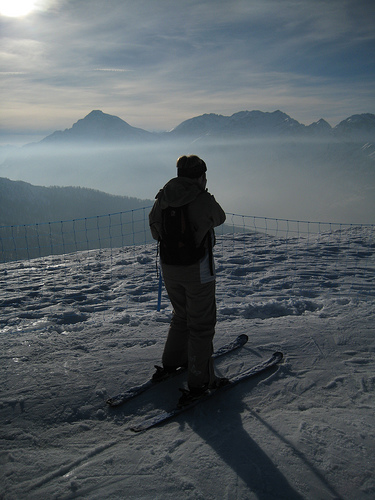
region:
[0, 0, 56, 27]
sun in the sky.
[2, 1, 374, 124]
the sky is blue.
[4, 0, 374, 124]
the sky is cloudy.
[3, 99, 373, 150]
mountains in the distance.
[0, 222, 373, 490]
snow covering the ground.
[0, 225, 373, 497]
the snow is white.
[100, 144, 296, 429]
one person is skiing.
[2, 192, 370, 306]
plastic fence on the hill.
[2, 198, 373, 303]
the fence is blue.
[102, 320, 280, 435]
two skis on person's feet.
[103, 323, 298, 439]
a man wearing skis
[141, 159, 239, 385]
a man wearing a one piece snow suit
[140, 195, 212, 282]
a man carrying a backpack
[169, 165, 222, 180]
a person wearing a warm head band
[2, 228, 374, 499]
snow on a hillside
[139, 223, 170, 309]
a person holding a blue ski pole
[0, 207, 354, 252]
a safety net to keep skiers safe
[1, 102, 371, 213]
a mountain range view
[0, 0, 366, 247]
a sunny and blue sky day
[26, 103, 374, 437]
skier on a hill overlooking a mountain range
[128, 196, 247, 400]
man in ski outfit wearing skis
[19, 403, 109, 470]
tracks in the white snow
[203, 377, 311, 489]
dark shadow cast by man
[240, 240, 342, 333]
pits in the white snow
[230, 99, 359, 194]
white mist in the distance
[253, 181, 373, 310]
net fence barrier erected in the snow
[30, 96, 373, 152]
dark mountain range in the distance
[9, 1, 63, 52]
the sun is on the left and is shining bright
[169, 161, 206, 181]
the man is wearing white ear protectors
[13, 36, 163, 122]
clouds are thin and white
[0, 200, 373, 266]
the blue net fence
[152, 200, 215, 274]
the backpack of the skier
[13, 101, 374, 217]
the hazy silhouetted mountains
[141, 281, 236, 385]
the tan snow pants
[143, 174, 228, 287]
the tan snow jacket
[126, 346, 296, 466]
the skier's right ski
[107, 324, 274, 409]
the skier's left ski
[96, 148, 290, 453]
A skier stands before mountains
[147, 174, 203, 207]
the hood of the jacket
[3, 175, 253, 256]
the forested foothills of the mountains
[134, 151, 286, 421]
skier observing mountain range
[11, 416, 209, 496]
ski tracks in snow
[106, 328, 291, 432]
snow-covered skis on skier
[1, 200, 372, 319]
blue plastic fencing on ledge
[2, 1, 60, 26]
sun shining through haze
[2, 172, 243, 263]
tree lined mountain range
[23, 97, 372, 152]
tips of mountains in distance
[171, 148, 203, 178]
winter hat on skier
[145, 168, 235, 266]
snow coat on skier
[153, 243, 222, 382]
snow pants on skier